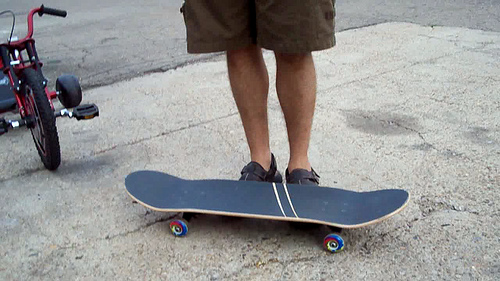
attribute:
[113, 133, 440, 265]
skateboard — multicolored, black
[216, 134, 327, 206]
shoe — black, brown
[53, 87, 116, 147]
pedal — black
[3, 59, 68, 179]
tire — black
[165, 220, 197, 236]
wheel — multi colored, red, black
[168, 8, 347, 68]
short — brown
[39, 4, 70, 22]
handle — black, red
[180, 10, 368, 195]
person — wearing, standing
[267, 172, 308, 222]
strip — white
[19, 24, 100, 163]
bike — red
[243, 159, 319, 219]
line — white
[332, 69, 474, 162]
pavement — spot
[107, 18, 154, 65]
asphalt — gray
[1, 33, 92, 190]
tricycle — black